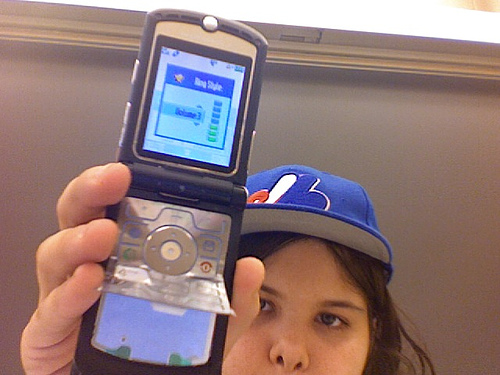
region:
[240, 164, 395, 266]
a blue white and orange baseball hat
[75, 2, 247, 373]
a flip phone cell phone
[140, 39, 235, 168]
the screen of a cell phone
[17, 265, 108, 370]
the finger of the person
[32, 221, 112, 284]
the finger of the person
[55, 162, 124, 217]
the finger of the person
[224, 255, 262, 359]
the thumb of a person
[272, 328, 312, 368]
the nose of a person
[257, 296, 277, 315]
the blue eye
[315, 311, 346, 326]
the blue eye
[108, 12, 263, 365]
black cell phone in photo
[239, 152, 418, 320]
person in blue hat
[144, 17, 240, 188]
blue and white screen on cell phone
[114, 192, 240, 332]
silver number pad peeling off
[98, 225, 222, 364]
second screen on cell phone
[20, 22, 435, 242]
wall is brown in photograph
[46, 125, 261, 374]
cell phone in persons hand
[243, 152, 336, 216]
red white blue emblem on blue hat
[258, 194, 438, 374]
person with brown hair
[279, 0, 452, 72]
lighted roof in photograph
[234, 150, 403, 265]
blue baseball cap on head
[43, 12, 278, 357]
hand holding cell phone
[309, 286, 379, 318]
nicely shaped dark eyebrow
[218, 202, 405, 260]
cap visor with white underside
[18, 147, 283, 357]
three fingers and a thumb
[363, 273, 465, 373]
whispy strands of dark hair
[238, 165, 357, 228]
blue orange and white logo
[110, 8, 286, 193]
flip cell phone screen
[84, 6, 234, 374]
cell phone with bent number pad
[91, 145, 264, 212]
hinge of flip type cell phone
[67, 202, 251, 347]
the keypad is broken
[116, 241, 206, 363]
the keypad is broken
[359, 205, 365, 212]
girl wearing blue cap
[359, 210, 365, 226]
girl wearing blue cap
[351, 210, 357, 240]
girl wearing blue cap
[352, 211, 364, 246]
girl wearing blue cap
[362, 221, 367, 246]
girl wearing blue cap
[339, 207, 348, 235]
girl wearing blue cap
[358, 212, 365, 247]
girl wearing blue cap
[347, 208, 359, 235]
girl wearing blue cap